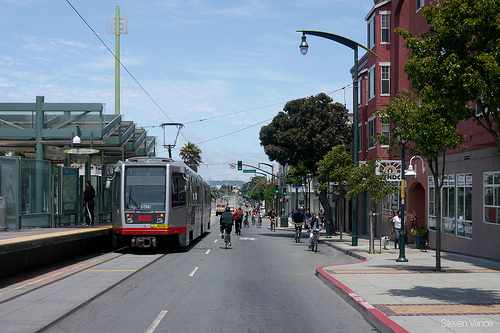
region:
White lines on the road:
[140, 227, 224, 330]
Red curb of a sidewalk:
[311, 253, 410, 331]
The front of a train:
[110, 156, 188, 255]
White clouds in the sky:
[2, 1, 374, 180]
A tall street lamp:
[294, 26, 388, 246]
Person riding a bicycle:
[217, 203, 237, 252]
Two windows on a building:
[376, 5, 396, 100]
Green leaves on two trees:
[371, 1, 497, 271]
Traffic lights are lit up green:
[233, 156, 290, 199]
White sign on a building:
[371, 154, 404, 186]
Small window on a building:
[375, 8, 387, 54]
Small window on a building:
[365, 18, 376, 52]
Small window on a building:
[378, 55, 395, 100]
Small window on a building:
[365, 64, 375, 104]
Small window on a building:
[350, 76, 364, 116]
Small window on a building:
[379, 109, 394, 146]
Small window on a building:
[358, 118, 383, 148]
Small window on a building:
[478, 168, 498, 229]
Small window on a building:
[455, 170, 477, 244]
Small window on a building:
[424, 173, 452, 237]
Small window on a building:
[450, 172, 477, 246]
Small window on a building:
[440, 170, 453, 247]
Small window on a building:
[373, 106, 386, 150]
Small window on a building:
[370, 56, 390, 109]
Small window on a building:
[374, 8, 396, 50]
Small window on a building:
[362, 19, 382, 61]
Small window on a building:
[363, 68, 381, 96]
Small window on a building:
[361, 118, 396, 156]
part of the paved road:
[60, 315, 121, 330]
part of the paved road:
[171, 310, 216, 330]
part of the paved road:
[224, 308, 275, 330]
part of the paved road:
[297, 310, 345, 327]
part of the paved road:
[286, 263, 308, 294]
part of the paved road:
[249, 253, 274, 272]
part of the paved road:
[152, 272, 175, 293]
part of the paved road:
[265, 237, 277, 244]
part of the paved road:
[241, 237, 252, 247]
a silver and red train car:
[111, 155, 210, 255]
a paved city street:
[43, 192, 385, 330]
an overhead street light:
[292, 26, 359, 56]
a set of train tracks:
[0, 241, 164, 332]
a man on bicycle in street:
[215, 205, 235, 250]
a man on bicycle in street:
[306, 211, 322, 253]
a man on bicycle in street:
[289, 205, 305, 242]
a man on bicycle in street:
[267, 206, 277, 232]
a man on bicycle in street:
[234, 206, 244, 233]